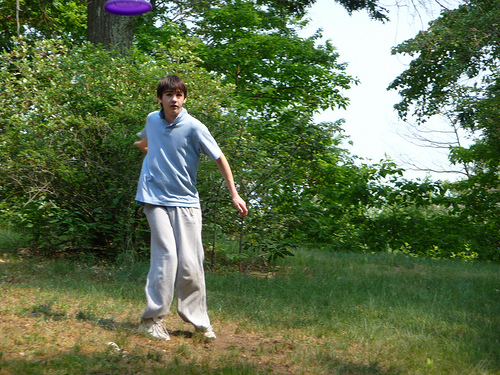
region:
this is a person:
[89, 49, 257, 372]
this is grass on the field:
[290, 264, 370, 327]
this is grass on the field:
[369, 258, 432, 350]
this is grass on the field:
[252, 288, 332, 372]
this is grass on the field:
[357, 258, 452, 302]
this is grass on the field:
[35, 280, 100, 350]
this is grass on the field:
[217, 276, 289, 337]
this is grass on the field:
[64, 263, 116, 323]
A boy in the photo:
[123, 80, 218, 357]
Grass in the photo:
[333, 254, 434, 324]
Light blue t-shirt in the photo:
[140, 125, 197, 203]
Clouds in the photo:
[356, 63, 397, 146]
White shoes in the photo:
[128, 306, 228, 351]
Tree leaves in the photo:
[240, 57, 320, 215]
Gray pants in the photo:
[141, 208, 206, 313]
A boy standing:
[110, 63, 256, 343]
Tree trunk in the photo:
[85, 20, 145, 70]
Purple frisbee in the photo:
[107, 0, 160, 24]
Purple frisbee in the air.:
[100, 0, 155, 15]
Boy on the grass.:
[125, 75, 245, 341]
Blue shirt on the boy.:
[130, 70, 226, 210]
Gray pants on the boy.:
[125, 75, 245, 341]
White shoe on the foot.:
[130, 310, 175, 341]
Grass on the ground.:
[0, 245, 495, 372]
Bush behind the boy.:
[0, 21, 255, 266]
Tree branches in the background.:
[400, 105, 475, 185]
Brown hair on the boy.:
[149, 70, 190, 125]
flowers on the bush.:
[0, 20, 94, 158]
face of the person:
[145, 68, 207, 122]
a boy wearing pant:
[124, 217, 243, 339]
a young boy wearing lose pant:
[130, 218, 217, 321]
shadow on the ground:
[13, 278, 137, 348]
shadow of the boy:
[19, 284, 113, 329]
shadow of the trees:
[33, 347, 143, 369]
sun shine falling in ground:
[228, 315, 325, 370]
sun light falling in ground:
[6, 300, 124, 369]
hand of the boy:
[211, 160, 261, 217]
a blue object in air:
[111, 5, 163, 25]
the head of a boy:
[154, 72, 195, 136]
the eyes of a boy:
[155, 89, 189, 105]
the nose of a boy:
[159, 84, 197, 106]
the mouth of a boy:
[165, 94, 185, 117]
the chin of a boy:
[159, 105, 183, 122]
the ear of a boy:
[149, 84, 171, 114]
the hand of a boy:
[218, 191, 271, 256]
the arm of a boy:
[181, 115, 261, 222]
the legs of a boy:
[112, 194, 246, 343]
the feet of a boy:
[127, 290, 252, 362]